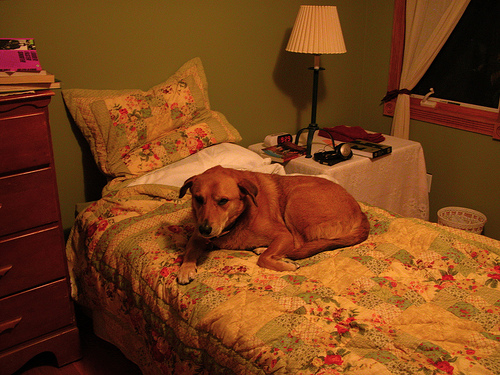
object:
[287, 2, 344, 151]
lamp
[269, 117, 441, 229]
table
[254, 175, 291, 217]
fur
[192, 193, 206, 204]
eye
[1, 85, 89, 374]
chest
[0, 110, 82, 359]
drawers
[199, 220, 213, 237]
nose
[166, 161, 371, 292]
dog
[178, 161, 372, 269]
dog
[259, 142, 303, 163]
book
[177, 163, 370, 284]
dog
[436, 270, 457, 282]
flower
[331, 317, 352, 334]
flower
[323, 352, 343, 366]
flower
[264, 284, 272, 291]
flower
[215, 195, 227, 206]
eye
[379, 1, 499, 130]
window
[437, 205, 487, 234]
trashcan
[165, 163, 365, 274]
dog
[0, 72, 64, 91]
books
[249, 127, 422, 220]
bedside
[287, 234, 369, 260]
tail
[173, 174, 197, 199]
ear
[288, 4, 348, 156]
lamp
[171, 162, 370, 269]
dog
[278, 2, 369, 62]
shade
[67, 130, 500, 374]
bed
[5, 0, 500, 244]
wall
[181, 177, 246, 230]
head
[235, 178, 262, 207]
ear